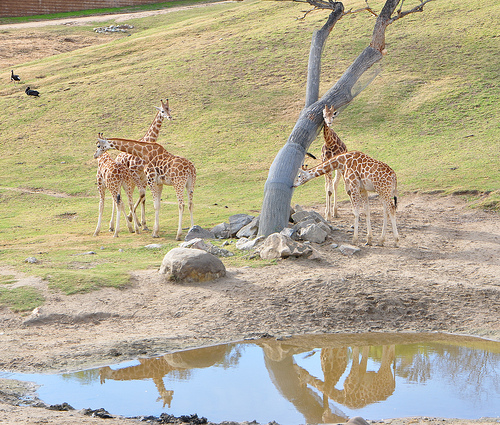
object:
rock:
[157, 243, 225, 285]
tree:
[254, 0, 430, 240]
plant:
[91, 14, 129, 40]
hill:
[195, 0, 500, 194]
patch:
[448, 241, 457, 249]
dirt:
[164, 194, 499, 334]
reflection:
[291, 344, 399, 424]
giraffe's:
[91, 129, 203, 240]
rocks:
[258, 230, 313, 260]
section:
[266, 140, 304, 188]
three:
[57, 74, 218, 243]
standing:
[147, 147, 195, 238]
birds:
[22, 86, 40, 100]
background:
[0, 0, 499, 424]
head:
[291, 163, 311, 189]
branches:
[387, 0, 439, 22]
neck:
[308, 152, 343, 180]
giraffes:
[316, 103, 351, 221]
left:
[7, 127, 39, 177]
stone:
[296, 224, 326, 245]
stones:
[289, 209, 313, 226]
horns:
[156, 99, 165, 108]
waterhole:
[1, 331, 499, 425]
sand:
[1, 198, 499, 372]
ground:
[0, 1, 499, 341]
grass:
[0, 0, 498, 313]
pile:
[258, 206, 324, 266]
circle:
[207, 208, 325, 267]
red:
[43, 8, 59, 13]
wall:
[2, 0, 157, 19]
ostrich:
[8, 69, 23, 84]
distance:
[27, 58, 45, 71]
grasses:
[366, 338, 491, 364]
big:
[91, 129, 197, 241]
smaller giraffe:
[93, 148, 140, 239]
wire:
[348, 67, 381, 99]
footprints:
[310, 275, 323, 286]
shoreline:
[158, 313, 395, 345]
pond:
[0, 329, 500, 425]